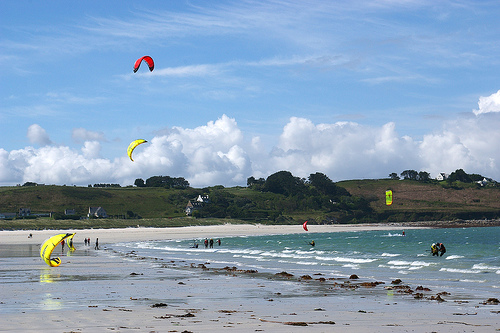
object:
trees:
[388, 173, 400, 181]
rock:
[349, 274, 360, 279]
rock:
[390, 279, 402, 285]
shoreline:
[99, 226, 499, 306]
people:
[216, 239, 221, 246]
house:
[436, 173, 445, 181]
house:
[477, 178, 489, 187]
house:
[329, 199, 337, 204]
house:
[87, 206, 109, 218]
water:
[0, 241, 500, 316]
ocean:
[114, 226, 500, 299]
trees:
[146, 175, 190, 189]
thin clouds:
[0, 0, 500, 96]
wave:
[377, 259, 439, 274]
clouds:
[0, 123, 112, 188]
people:
[430, 243, 439, 257]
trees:
[201, 188, 209, 193]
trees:
[134, 178, 144, 187]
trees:
[88, 184, 92, 188]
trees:
[16, 184, 20, 187]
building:
[0, 206, 127, 220]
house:
[185, 195, 211, 216]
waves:
[215, 246, 381, 270]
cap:
[435, 242, 439, 246]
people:
[204, 238, 209, 249]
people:
[84, 238, 88, 246]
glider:
[385, 189, 393, 206]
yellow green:
[385, 189, 392, 206]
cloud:
[471, 90, 498, 116]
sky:
[0, 0, 500, 183]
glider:
[39, 233, 73, 267]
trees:
[22, 181, 37, 186]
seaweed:
[284, 322, 309, 326]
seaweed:
[151, 303, 167, 308]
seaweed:
[358, 310, 374, 313]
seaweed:
[130, 272, 143, 275]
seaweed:
[453, 312, 477, 315]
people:
[195, 244, 198, 249]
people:
[435, 242, 446, 257]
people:
[209, 239, 214, 249]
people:
[29, 233, 32, 238]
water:
[107, 225, 499, 299]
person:
[309, 240, 316, 247]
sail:
[303, 220, 308, 231]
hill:
[0, 169, 500, 230]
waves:
[112, 239, 231, 253]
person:
[402, 230, 405, 235]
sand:
[0, 227, 500, 333]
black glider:
[127, 139, 148, 162]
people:
[94, 238, 99, 250]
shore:
[0, 224, 500, 333]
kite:
[133, 55, 154, 73]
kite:
[127, 139, 148, 162]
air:
[1, 0, 499, 188]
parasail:
[66, 233, 76, 252]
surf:
[133, 242, 397, 270]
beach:
[0, 219, 500, 333]